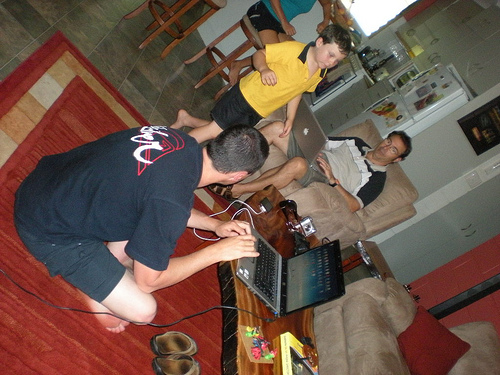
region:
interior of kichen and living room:
[5, 7, 499, 367]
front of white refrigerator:
[337, 65, 457, 155]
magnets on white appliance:
[379, 68, 451, 131]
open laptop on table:
[233, 238, 342, 313]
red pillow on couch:
[328, 281, 497, 373]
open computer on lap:
[296, 98, 330, 178]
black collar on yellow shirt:
[243, 41, 330, 116]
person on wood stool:
[193, 3, 298, 98]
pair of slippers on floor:
[151, 329, 198, 373]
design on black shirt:
[18, 124, 203, 274]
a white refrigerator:
[329, 62, 466, 133]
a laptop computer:
[234, 217, 346, 318]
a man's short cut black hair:
[202, 122, 269, 178]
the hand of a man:
[222, 225, 261, 264]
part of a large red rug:
[0, 33, 235, 373]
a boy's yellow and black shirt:
[240, 30, 329, 136]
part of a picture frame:
[452, 91, 494, 156]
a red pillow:
[397, 312, 473, 374]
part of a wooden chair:
[187, 3, 306, 100]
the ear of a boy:
[317, 34, 326, 49]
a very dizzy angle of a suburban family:
[7, 7, 490, 371]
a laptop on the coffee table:
[230, 214, 347, 316]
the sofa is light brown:
[312, 267, 497, 374]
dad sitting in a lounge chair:
[223, 93, 419, 245]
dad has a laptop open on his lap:
[284, 98, 338, 188]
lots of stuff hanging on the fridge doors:
[356, 60, 476, 132]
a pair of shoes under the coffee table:
[143, 324, 207, 373]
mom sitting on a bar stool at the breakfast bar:
[183, 0, 320, 90]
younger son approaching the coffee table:
[168, 18, 357, 146]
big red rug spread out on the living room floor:
[0, 25, 228, 372]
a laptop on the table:
[225, 190, 374, 357]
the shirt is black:
[22, 99, 174, 284]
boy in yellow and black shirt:
[170, 25, 352, 136]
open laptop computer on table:
[236, 220, 346, 317]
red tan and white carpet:
[0, 30, 260, 374]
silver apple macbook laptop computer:
[290, 97, 325, 164]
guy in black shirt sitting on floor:
[16, 119, 270, 333]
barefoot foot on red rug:
[75, 287, 131, 332]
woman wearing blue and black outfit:
[227, 0, 332, 86]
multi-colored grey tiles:
[0, 0, 272, 209]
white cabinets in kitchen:
[312, 0, 498, 282]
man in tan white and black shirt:
[235, 132, 414, 211]